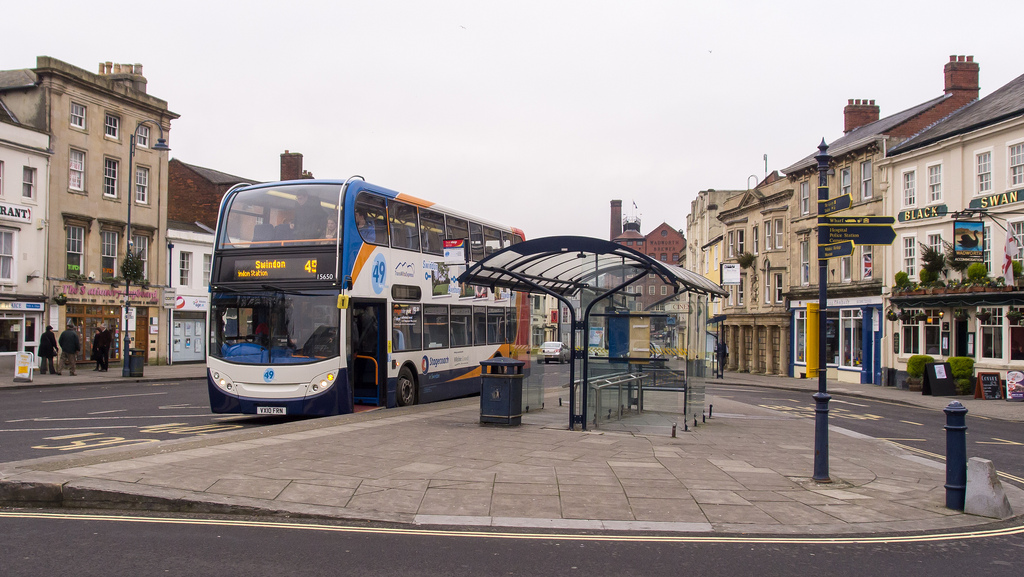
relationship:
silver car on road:
[538, 332, 577, 361] [528, 362, 624, 384]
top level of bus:
[204, 179, 531, 251] [206, 179, 531, 409]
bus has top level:
[206, 179, 531, 409] [204, 179, 531, 251]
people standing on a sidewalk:
[33, 316, 126, 379] [6, 355, 197, 377]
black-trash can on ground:
[475, 350, 530, 426] [101, 376, 966, 534]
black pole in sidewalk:
[796, 135, 846, 484] [689, 390, 890, 527]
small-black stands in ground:
[663, 402, 720, 441] [622, 387, 759, 496]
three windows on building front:
[54, 89, 161, 148] [39, 55, 173, 369]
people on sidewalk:
[35, 312, 120, 375] [0, 353, 204, 379]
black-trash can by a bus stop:
[476, 350, 531, 426] [468, 238, 724, 405]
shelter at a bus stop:
[463, 242, 719, 426] [470, 225, 721, 426]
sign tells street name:
[811, 136, 904, 478] [828, 208, 898, 226]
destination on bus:
[230, 249, 324, 288] [211, 186, 534, 428]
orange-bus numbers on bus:
[302, 259, 318, 275] [211, 186, 534, 428]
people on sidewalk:
[37, 323, 59, 374] [1, 355, 218, 382]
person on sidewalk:
[62, 322, 82, 366] [1, 355, 218, 382]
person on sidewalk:
[88, 322, 106, 364] [1, 355, 218, 382]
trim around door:
[854, 303, 889, 399] [859, 314, 872, 382]